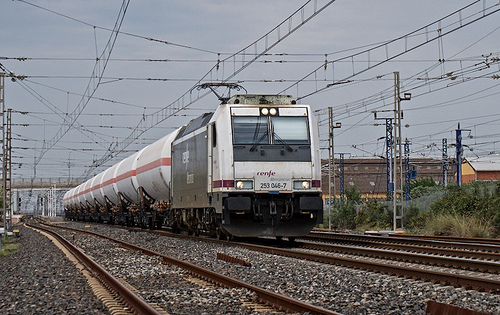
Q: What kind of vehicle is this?
A: Train.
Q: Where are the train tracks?
A: On the ground.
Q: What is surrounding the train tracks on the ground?
A: Gravel.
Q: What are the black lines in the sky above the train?
A: Power lines.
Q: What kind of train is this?
A: Freight train.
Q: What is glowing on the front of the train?
A: Headlights.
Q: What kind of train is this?
A: Freight train.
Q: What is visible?
A: Train.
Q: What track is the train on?
A: The track in the middle.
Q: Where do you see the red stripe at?
A: The red stripe in the middle in back of train.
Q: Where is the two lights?
A: The two lights are on the front of train.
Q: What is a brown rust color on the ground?
A: The train tracks.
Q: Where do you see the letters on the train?
A: The letters are in the front of train.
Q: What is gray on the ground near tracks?
A: The gravel is gray on the tracks near train.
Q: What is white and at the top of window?
A: There are two lights at top of window.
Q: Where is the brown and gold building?
A: Brown and gold building is on the right side of train.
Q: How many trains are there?
A: One.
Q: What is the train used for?
A: Transportation.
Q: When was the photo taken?
A: Daytime.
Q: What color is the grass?
A: Green.